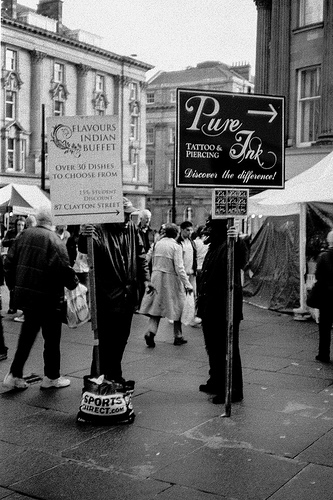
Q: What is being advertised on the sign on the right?
A: Pure Ink Tattoo and Piercing.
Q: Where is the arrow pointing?
A: Right.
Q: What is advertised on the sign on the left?
A: Flavours Indian Buffet.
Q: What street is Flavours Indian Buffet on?
A: Clayton.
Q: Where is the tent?
A: In front of the building.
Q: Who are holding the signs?
A: Two men.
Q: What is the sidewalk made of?
A: Concrete tiles.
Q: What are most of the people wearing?
A: Coats.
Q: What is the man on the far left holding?
A: A bag.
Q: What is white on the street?
A: The tent.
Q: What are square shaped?
A: The tiles.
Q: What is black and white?
A: The photo is black and white.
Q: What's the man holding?
A: A sign.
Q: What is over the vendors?
A: A canopy.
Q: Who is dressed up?
A: The man.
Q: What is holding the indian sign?
A: The man.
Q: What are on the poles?
A: Signs.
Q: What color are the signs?
A: Black and white.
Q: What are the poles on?
A: The sidewalk.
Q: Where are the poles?
A: On the sidewalk.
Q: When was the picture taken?
A: Daytime.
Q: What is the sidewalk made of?
A: Cement.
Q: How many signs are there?
A: Two.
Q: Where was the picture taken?
A: On the sidewalk.